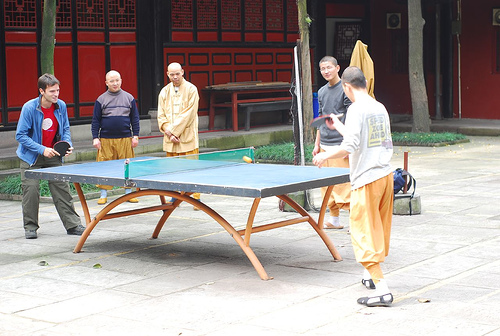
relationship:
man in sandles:
[17, 56, 409, 312] [99, 195, 139, 207]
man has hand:
[17, 56, 409, 312] [159, 94, 196, 146]